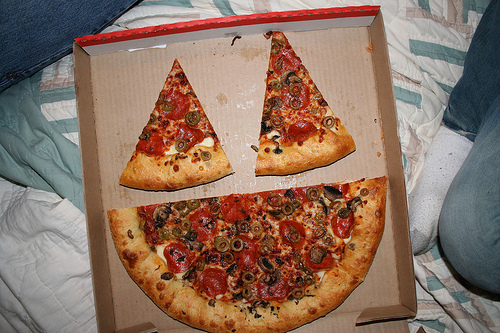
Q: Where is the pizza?
A: In box.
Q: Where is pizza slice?
A: In box.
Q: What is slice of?
A: Pizza.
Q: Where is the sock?
A: By box.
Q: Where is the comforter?
A: On bed.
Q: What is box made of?
A: Cardboard.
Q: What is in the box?
A: Pizza.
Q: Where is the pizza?
A: In the box.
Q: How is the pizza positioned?
A: In a smiley face.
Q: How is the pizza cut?
A: In slices.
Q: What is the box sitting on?
A: A blanket.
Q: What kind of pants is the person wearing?
A: Jeans.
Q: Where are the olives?
A: On the pizza.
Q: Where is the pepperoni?
A: On the pizza.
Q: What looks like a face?
A: The pizza.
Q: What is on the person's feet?
A: A sock.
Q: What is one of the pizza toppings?
A: Pepperoni.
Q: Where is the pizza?
A: In a box.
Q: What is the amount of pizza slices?
A: Three.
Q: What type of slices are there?
A: One big two small.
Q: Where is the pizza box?
A: On a bed.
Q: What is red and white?
A: The pizza box.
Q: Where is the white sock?
A: Next to pizza box.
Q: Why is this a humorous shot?
A: The pizza looks like a sailboat, or a bikini.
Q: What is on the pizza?
A: Pepperoni slices, mushrooms and olives.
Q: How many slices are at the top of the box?
A: Two.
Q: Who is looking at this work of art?
A: The photographer.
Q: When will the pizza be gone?
A: When it is entirely eaten.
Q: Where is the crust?
A: On the edge of the pizza.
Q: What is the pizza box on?
A: A bed.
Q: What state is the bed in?
A: It's unmade.